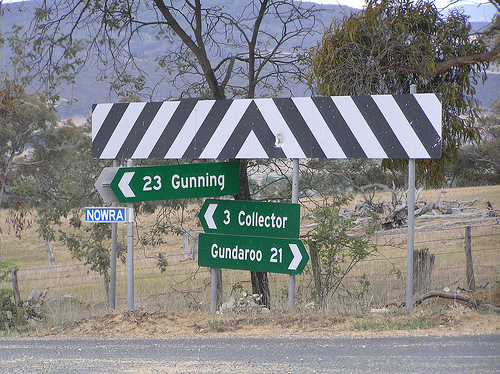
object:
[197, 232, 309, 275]
sign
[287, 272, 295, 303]
post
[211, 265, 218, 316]
post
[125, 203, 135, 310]
post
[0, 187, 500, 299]
hill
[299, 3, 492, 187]
trees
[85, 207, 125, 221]
blue sign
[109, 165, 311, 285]
signs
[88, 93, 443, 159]
sign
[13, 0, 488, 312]
tree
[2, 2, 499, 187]
leaves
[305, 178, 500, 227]
pile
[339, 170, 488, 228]
branches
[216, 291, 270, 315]
rocks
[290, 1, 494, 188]
tree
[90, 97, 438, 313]
barrier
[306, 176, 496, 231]
branch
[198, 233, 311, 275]
gundaroo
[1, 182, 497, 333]
field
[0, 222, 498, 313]
fence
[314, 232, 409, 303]
fence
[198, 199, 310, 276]
sign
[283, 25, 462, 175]
tree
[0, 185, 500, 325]
ground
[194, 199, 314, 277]
signs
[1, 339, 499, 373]
road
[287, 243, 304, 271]
arrow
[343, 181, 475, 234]
tree branches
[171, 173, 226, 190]
gunning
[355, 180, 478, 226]
sticks